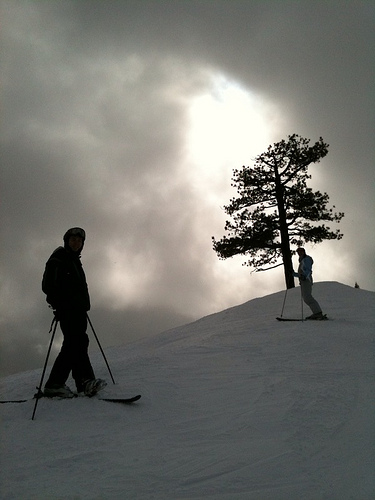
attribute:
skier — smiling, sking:
[41, 224, 114, 398]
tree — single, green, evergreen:
[211, 132, 347, 291]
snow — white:
[222, 350, 333, 499]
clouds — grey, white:
[90, 66, 194, 178]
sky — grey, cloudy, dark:
[1, 2, 374, 380]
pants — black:
[53, 309, 95, 392]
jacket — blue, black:
[41, 246, 90, 330]